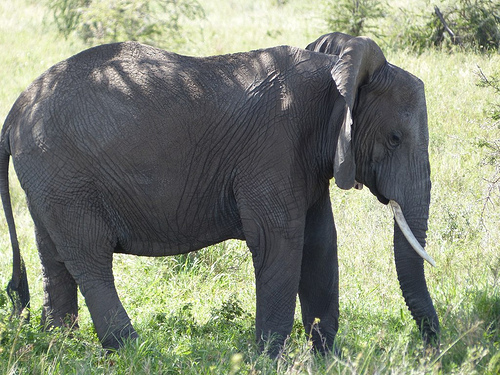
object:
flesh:
[183, 107, 255, 227]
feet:
[97, 336, 149, 365]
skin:
[86, 103, 249, 228]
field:
[1, 2, 500, 375]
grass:
[56, 312, 220, 373]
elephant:
[0, 32, 440, 367]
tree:
[399, 0, 499, 55]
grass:
[403, 44, 497, 73]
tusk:
[386, 197, 442, 269]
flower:
[309, 315, 325, 330]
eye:
[390, 134, 399, 144]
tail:
[0, 127, 34, 333]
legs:
[33, 203, 138, 360]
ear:
[331, 34, 384, 190]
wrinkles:
[44, 57, 427, 289]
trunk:
[392, 201, 444, 351]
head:
[330, 36, 448, 351]